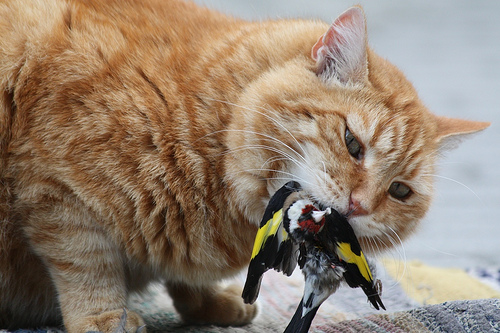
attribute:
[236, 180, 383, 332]
bird — black, yellow, dead, striped, small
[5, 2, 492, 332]
cat — orange, white, standing, fat, striped, tabby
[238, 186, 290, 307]
wing — black, yellow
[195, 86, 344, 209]
whiskers — white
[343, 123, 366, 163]
eye — green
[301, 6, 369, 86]
ear — orange